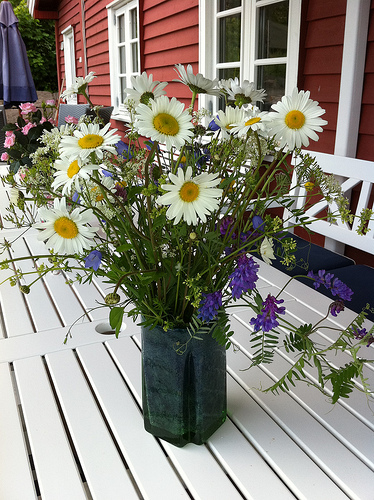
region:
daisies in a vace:
[56, 72, 304, 444]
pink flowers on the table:
[0, 96, 77, 184]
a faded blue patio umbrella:
[0, 2, 37, 106]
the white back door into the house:
[57, 27, 81, 102]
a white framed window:
[103, 0, 146, 122]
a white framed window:
[196, 1, 298, 140]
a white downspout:
[322, 2, 363, 255]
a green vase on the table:
[134, 307, 232, 449]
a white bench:
[237, 134, 372, 260]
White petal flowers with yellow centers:
[263, 87, 328, 150]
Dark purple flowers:
[306, 269, 356, 302]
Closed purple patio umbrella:
[0, 0, 39, 106]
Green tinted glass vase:
[137, 306, 229, 448]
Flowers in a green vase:
[4, 63, 372, 447]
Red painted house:
[24, 0, 372, 269]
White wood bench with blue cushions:
[222, 147, 372, 324]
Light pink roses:
[0, 100, 79, 162]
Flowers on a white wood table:
[1, 156, 373, 499]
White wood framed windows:
[103, 0, 146, 126]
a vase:
[140, 328, 221, 439]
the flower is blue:
[311, 269, 358, 299]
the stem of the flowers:
[142, 271, 192, 316]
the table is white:
[236, 410, 370, 489]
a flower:
[165, 170, 222, 227]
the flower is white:
[154, 167, 224, 226]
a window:
[209, 22, 244, 75]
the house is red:
[141, 9, 201, 62]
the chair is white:
[333, 159, 372, 199]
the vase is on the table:
[137, 333, 227, 443]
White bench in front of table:
[226, 148, 373, 318]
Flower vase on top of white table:
[0, 70, 371, 447]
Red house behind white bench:
[24, 0, 373, 268]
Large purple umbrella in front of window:
[0, 0, 39, 106]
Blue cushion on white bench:
[248, 227, 353, 277]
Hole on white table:
[95, 320, 123, 333]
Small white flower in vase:
[153, 165, 225, 226]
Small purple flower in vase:
[197, 287, 221, 319]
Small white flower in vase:
[260, 86, 331, 152]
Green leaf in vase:
[108, 305, 122, 327]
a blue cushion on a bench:
[241, 222, 352, 273]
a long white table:
[1, 165, 372, 497]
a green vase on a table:
[134, 312, 234, 447]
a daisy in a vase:
[158, 165, 228, 228]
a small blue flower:
[82, 248, 102, 269]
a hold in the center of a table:
[94, 318, 128, 336]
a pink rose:
[17, 99, 37, 115]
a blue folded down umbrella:
[0, 0, 41, 109]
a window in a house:
[106, 0, 147, 120]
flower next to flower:
[157, 167, 222, 223]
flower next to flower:
[33, 194, 98, 258]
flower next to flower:
[61, 118, 118, 160]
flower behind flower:
[126, 72, 165, 111]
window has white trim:
[104, 2, 149, 125]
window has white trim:
[196, 1, 304, 157]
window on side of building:
[196, 1, 300, 159]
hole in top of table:
[95, 319, 124, 336]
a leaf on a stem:
[105, 306, 126, 339]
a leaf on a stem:
[265, 332, 279, 340]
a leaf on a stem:
[270, 387, 276, 400]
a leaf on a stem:
[273, 386, 282, 398]